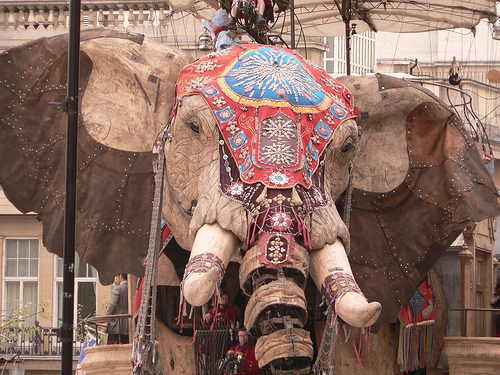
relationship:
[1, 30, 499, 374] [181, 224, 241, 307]
elephant has tusk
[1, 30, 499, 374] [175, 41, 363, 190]
elephant dressed with fabric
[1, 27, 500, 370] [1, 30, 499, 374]
elephant sitting on elephant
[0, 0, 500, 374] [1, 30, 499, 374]
building behind elephant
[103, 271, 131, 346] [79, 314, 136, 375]
man standing on balcony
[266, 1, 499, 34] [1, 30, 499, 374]
awning above elephant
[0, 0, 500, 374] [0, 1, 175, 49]
building has balcony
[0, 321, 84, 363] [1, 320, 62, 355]
balcony has railing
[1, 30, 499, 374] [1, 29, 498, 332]
elephant has head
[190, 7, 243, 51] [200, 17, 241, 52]
man wearing a gown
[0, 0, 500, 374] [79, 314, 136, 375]
building has balcony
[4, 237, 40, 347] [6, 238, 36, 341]
window has curtains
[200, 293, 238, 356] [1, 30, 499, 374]
man inside of elephant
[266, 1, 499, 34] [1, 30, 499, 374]
awning over elephant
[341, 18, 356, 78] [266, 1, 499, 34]
pole holding up awning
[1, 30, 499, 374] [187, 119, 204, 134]
elephant has right eye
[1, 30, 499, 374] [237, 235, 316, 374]
elephant has trunk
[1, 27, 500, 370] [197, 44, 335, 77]
elephant on elephants back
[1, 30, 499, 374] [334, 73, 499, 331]
elephant has left ear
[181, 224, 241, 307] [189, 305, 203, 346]
tusk has ribbon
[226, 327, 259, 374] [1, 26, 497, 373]
man under statue